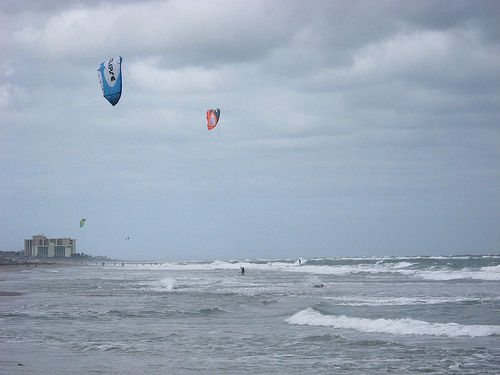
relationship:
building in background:
[16, 234, 86, 261] [1, 215, 139, 267]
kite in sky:
[77, 50, 138, 120] [1, 1, 498, 260]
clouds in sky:
[2, 1, 499, 184] [1, 1, 498, 260]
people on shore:
[13, 258, 155, 270] [0, 249, 169, 267]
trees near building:
[77, 252, 108, 258] [16, 234, 86, 261]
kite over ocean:
[92, 47, 127, 109] [1, 255, 498, 374]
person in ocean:
[236, 266, 251, 280] [1, 255, 498, 374]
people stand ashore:
[13, 258, 155, 270] [0, 249, 169, 267]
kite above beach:
[77, 217, 87, 228] [0, 249, 169, 267]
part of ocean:
[8, 269, 390, 375] [1, 255, 498, 374]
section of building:
[25, 235, 77, 256] [16, 234, 86, 261]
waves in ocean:
[286, 307, 500, 334] [1, 255, 498, 374]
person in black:
[236, 266, 251, 280] [296, 258, 302, 264]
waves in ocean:
[291, 307, 500, 334] [1, 255, 498, 374]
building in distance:
[16, 234, 86, 261] [25, 237, 83, 269]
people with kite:
[13, 258, 155, 270] [92, 47, 127, 109]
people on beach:
[13, 258, 155, 270] [1, 256, 162, 271]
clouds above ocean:
[2, 1, 499, 184] [1, 255, 498, 374]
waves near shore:
[130, 257, 500, 283] [0, 249, 169, 267]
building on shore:
[16, 234, 86, 261] [0, 249, 169, 267]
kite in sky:
[197, 104, 224, 132] [1, 1, 498, 260]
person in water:
[122, 261, 126, 267] [1, 255, 498, 374]